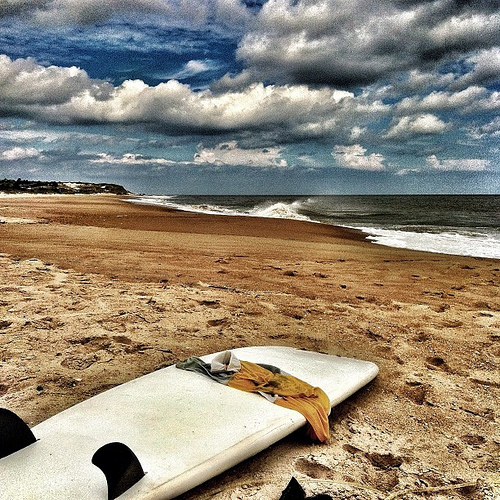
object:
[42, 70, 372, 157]
cloud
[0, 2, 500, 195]
sky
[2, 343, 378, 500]
surfboard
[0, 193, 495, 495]
beach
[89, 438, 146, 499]
fin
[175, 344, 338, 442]
clothes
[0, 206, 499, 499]
sand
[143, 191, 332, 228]
waves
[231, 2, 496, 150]
clouds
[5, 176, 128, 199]
outcropping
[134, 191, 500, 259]
ocean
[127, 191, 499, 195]
horizon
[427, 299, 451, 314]
footprints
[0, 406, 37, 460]
fins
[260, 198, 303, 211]
caps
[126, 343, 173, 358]
sticks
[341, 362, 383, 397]
edge